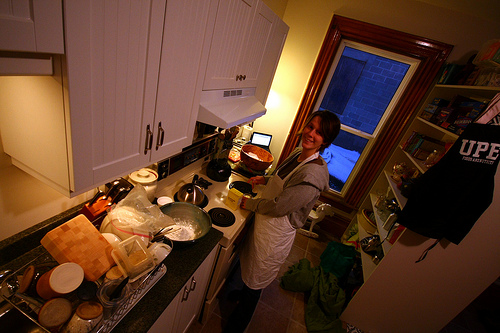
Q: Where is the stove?
A: Kitchen.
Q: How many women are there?
A: One.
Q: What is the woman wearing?
A: Apron.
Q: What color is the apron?
A: White.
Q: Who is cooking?
A: The woman in the apron.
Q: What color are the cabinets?
A: White.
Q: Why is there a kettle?
A: Boil water.